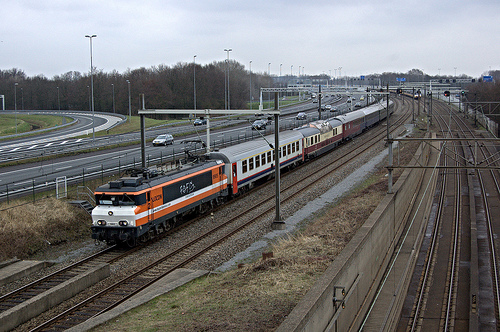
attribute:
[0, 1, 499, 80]
sky — pale, cloudy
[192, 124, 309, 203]
carriage — pale, gray, pulled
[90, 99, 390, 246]
train — passenger, running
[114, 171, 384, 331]
grass — dead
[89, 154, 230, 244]
train engine — orange, white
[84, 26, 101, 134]
lighting — stadium style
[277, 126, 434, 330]
barrier — tall, cement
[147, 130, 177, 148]
car — driving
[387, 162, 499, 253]
tracks — train tracks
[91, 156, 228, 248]
engine train — orange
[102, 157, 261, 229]
train — white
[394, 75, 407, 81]
billboard — blue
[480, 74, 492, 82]
billboard — blue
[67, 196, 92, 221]
stairs — cement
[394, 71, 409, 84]
signs — blue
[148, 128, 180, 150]
car — white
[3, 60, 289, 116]
trees — leafless, brown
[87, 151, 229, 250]
engine — orange, black, white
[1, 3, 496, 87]
sky — grey, cloudy